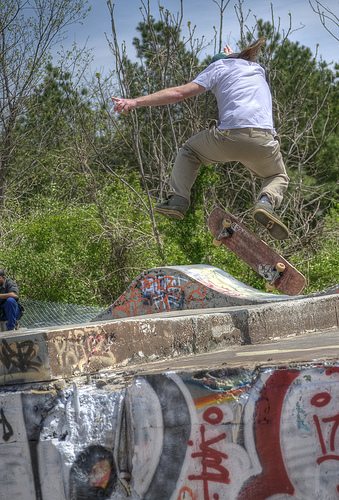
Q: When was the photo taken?
A: Afternoon.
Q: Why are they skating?
A: For fun.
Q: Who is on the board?
A: A guy.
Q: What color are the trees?
A: Green.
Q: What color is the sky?
A: Blue.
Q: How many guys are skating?
A: One.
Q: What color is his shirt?
A: White.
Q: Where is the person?
A: At the skatepark.